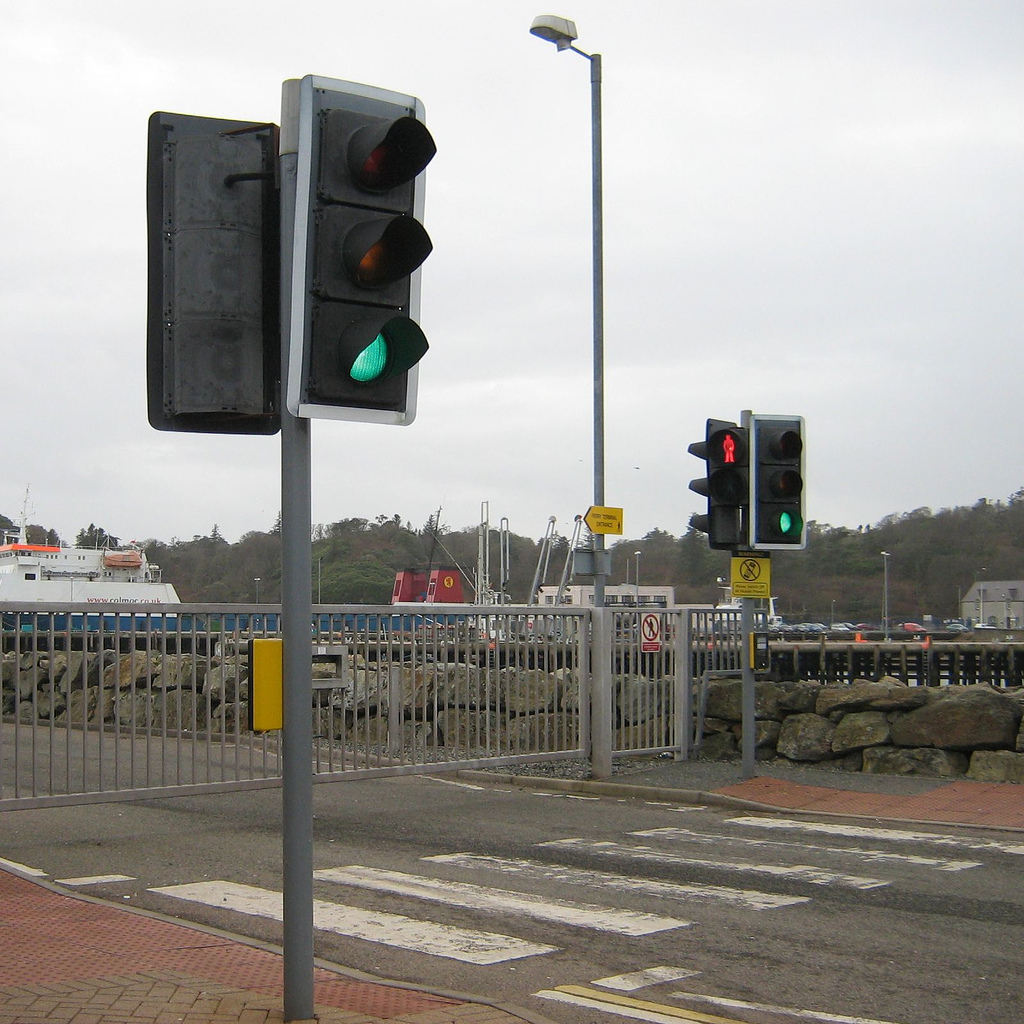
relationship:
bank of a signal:
[118, 44, 490, 529] [151, 67, 423, 435]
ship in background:
[0, 534, 188, 611] [19, 478, 292, 805]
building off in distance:
[960, 580, 1018, 631] [905, 513, 1020, 758]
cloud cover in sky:
[522, 156, 985, 378] [3, 7, 1016, 527]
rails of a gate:
[8, 614, 761, 783] [598, 602, 760, 783]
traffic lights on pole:
[142, 71, 437, 441] [278, 79, 321, 1013]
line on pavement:
[727, 807, 1021, 862] [12, 730, 1000, 1015]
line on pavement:
[639, 819, 963, 870] [0, 728, 965, 954]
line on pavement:
[543, 833, 897, 897] [12, 730, 1000, 1015]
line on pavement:
[424, 844, 814, 914] [9, 731, 993, 981]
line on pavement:
[310, 857, 691, 937] [98, 725, 1015, 937]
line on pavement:
[3, 759, 1010, 1019] [145, 876, 572, 966]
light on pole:
[138, 70, 433, 434] [277, 77, 329, 1019]